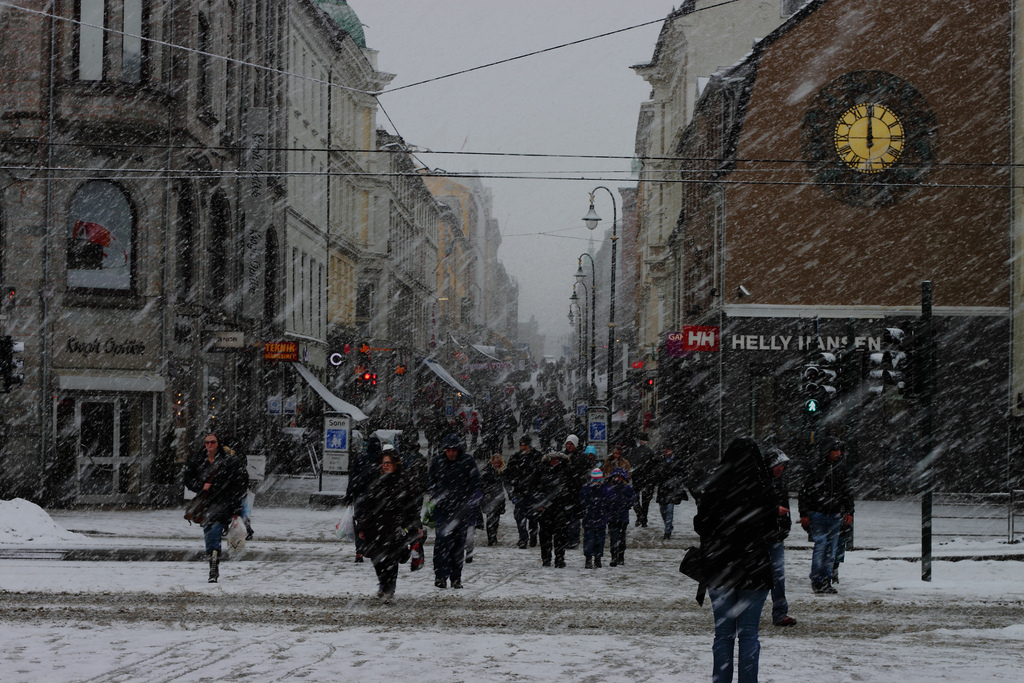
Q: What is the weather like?
A: It is cloudy.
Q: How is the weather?
A: It is cloudy.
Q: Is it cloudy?
A: Yes, it is cloudy.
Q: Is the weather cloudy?
A: Yes, it is cloudy.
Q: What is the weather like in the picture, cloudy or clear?
A: It is cloudy.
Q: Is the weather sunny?
A: No, it is cloudy.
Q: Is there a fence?
A: No, there are no fences.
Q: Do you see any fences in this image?
A: No, there are no fences.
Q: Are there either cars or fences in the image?
A: No, there are no fences or cars.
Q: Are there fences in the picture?
A: No, there are no fences.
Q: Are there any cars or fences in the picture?
A: No, there are no fences or cars.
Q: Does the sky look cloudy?
A: Yes, the sky is cloudy.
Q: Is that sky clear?
A: No, the sky is cloudy.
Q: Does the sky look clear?
A: No, the sky is cloudy.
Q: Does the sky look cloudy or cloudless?
A: The sky is cloudy.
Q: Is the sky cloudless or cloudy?
A: The sky is cloudy.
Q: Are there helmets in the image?
A: No, there are no helmets.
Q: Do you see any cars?
A: No, there are no cars.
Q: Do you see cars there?
A: No, there are no cars.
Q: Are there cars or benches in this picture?
A: No, there are no cars or benches.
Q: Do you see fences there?
A: No, there are no fences.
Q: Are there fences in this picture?
A: No, there are no fences.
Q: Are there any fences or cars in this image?
A: No, there are no fences or cars.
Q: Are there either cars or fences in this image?
A: No, there are no fences or cars.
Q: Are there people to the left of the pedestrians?
A: Yes, there are people to the left of the pedestrians.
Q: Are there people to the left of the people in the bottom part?
A: Yes, there are people to the left of the pedestrians.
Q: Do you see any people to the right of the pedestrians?
A: No, the people are to the left of the pedestrians.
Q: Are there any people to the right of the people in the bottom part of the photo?
A: No, the people are to the left of the pedestrians.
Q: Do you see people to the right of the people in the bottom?
A: No, the people are to the left of the pedestrians.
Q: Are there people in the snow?
A: Yes, there are people in the snow.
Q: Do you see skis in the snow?
A: No, there are people in the snow.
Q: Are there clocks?
A: Yes, there is a clock.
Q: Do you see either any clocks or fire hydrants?
A: Yes, there is a clock.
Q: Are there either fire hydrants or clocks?
A: Yes, there is a clock.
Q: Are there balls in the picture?
A: No, there are no balls.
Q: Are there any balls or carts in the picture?
A: No, there are no balls or carts.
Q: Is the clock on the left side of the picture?
A: No, the clock is on the right of the image.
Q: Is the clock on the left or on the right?
A: The clock is on the right of the image.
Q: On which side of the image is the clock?
A: The clock is on the right of the image.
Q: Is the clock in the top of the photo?
A: Yes, the clock is in the top of the image.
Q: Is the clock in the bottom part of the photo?
A: No, the clock is in the top of the image.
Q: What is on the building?
A: The clock is on the building.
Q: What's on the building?
A: The clock is on the building.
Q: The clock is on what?
A: The clock is on the building.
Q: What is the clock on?
A: The clock is on the building.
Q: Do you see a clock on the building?
A: Yes, there is a clock on the building.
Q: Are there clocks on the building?
A: Yes, there is a clock on the building.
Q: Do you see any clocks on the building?
A: Yes, there is a clock on the building.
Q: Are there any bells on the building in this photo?
A: No, there is a clock on the building.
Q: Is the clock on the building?
A: Yes, the clock is on the building.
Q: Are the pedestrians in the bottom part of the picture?
A: Yes, the pedestrians are in the bottom of the image.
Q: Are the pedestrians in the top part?
A: No, the pedestrians are in the bottom of the image.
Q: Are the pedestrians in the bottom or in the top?
A: The pedestrians are in the bottom of the image.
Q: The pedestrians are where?
A: The pedestrians are on the snow.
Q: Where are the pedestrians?
A: The pedestrians are on the snow.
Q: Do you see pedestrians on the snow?
A: Yes, there are pedestrians on the snow.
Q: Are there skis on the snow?
A: No, there are pedestrians on the snow.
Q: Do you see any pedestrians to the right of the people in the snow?
A: Yes, there are pedestrians to the right of the people.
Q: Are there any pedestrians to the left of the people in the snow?
A: No, the pedestrians are to the right of the people.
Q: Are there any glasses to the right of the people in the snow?
A: No, there are pedestrians to the right of the people.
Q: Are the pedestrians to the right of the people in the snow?
A: Yes, the pedestrians are to the right of the people.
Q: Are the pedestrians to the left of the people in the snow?
A: No, the pedestrians are to the right of the people.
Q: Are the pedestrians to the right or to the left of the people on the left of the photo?
A: The pedestrians are to the right of the people.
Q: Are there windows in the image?
A: Yes, there is a window.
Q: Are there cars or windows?
A: Yes, there is a window.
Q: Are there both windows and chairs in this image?
A: No, there is a window but no chairs.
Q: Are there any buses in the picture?
A: No, there are no buses.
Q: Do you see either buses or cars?
A: No, there are no buses or cars.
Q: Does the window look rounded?
A: Yes, the window is rounded.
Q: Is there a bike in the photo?
A: No, there are no bikes.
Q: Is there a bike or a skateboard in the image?
A: No, there are no bikes or skateboards.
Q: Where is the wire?
A: The wire is on the snow.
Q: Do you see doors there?
A: Yes, there are doors.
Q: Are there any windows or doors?
A: Yes, there are doors.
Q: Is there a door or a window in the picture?
A: Yes, there are doors.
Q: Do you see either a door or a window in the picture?
A: Yes, there are doors.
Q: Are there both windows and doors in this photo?
A: Yes, there are both doors and a window.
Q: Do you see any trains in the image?
A: No, there are no trains.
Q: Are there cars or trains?
A: No, there are no trains or cars.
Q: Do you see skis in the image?
A: No, there are no skis.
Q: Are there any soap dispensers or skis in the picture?
A: No, there are no skis or soap dispensers.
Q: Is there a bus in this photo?
A: No, there are no buses.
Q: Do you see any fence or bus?
A: No, there are no buses or fences.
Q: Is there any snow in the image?
A: Yes, there is snow.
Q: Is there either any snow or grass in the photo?
A: Yes, there is snow.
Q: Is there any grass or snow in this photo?
A: Yes, there is snow.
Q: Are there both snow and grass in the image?
A: No, there is snow but no grass.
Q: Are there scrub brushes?
A: No, there are no scrub brushes.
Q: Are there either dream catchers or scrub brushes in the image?
A: No, there are no scrub brushes or dream catchers.